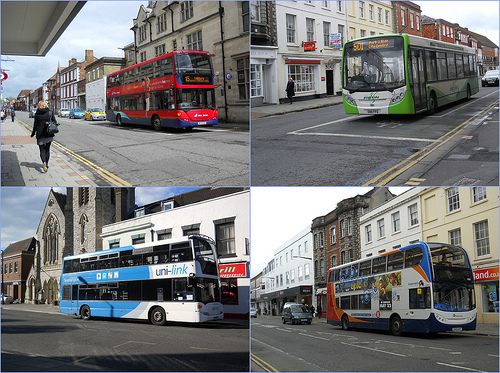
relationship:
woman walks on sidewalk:
[29, 90, 56, 178] [2, 111, 102, 188]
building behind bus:
[252, 220, 317, 293] [323, 238, 480, 338]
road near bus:
[18, 110, 248, 185] [58, 233, 225, 327]